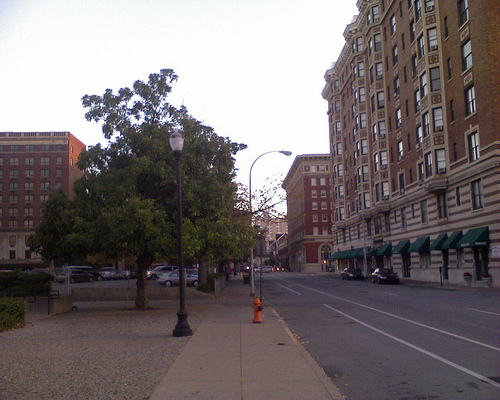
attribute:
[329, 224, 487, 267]
shades — green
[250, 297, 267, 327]
hydrant. — red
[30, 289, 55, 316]
stairwell — downwards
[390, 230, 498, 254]
awnings — green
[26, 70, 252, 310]
tree — huge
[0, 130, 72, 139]
writing — large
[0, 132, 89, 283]
building — brown and tall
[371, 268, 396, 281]
car — black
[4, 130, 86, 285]
building — highrise, brick, red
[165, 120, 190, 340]
street light — black, iron, decorative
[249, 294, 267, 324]
hydrant — orange and black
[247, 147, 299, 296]
street light — curved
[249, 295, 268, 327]
hydrant — orange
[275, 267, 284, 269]
headlights — on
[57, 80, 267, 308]
tree — large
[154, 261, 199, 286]
car — silver, parked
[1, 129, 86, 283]
brick building — red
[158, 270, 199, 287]
car — several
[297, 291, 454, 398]
line — white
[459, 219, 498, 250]
shade — green, exterior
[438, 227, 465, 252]
shade — exterior, green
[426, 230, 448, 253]
shade — exterior, green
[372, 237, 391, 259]
shade — exterior, green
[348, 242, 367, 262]
shade — exterior, green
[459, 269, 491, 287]
flower pots — red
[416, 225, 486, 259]
awnings — green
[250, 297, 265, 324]
fire hydrant — red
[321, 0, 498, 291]
building — large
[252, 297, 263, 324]
fire hydrant — orange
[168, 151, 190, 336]
pole — black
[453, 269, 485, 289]
planter — cement